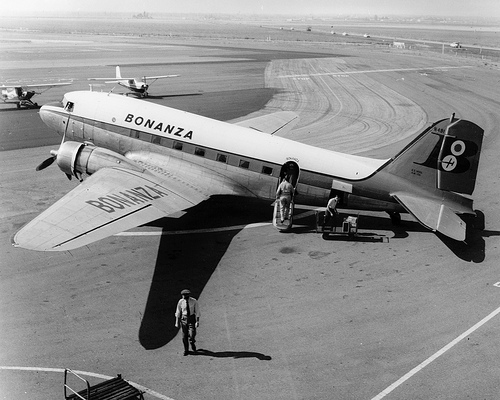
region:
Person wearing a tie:
[155, 279, 222, 363]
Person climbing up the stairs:
[265, 168, 299, 235]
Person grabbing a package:
[317, 186, 349, 250]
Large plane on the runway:
[7, 68, 498, 338]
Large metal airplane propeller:
[23, 111, 95, 189]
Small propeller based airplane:
[76, 56, 183, 103]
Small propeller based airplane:
[0, 66, 70, 111]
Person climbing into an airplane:
[263, 167, 308, 237]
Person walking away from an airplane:
[168, 281, 213, 368]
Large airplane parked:
[3, 67, 493, 285]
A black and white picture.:
[26, 22, 491, 371]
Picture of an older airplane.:
[23, 57, 497, 364]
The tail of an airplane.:
[399, 106, 487, 264]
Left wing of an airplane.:
[18, 174, 253, 263]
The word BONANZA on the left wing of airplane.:
[75, 178, 182, 213]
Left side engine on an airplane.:
[42, 105, 132, 180]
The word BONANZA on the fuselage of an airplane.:
[119, 103, 202, 145]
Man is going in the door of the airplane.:
[266, 148, 308, 250]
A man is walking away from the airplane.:
[169, 285, 216, 355]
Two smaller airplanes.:
[6, 63, 172, 112]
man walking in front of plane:
[159, 265, 222, 367]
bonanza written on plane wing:
[73, 177, 178, 220]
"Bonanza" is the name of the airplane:
[125, 113, 199, 141]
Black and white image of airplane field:
[0, 13, 497, 393]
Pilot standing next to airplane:
[170, 286, 207, 356]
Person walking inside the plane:
[263, 158, 298, 235]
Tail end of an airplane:
[402, 109, 484, 261]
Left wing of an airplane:
[16, 161, 245, 296]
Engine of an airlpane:
[30, 133, 116, 179]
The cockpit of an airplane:
[38, 90, 98, 137]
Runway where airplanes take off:
[252, 47, 434, 179]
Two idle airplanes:
[0, 65, 172, 122]